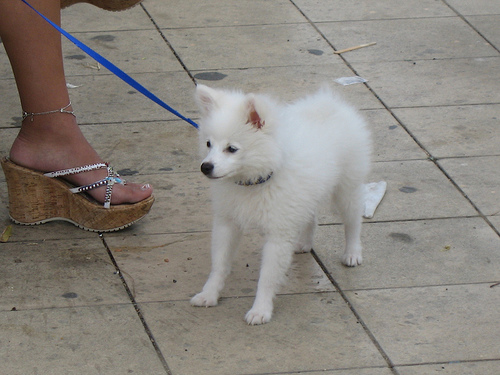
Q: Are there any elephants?
A: No, there are no elephants.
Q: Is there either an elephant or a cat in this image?
A: No, there are no elephants or cats.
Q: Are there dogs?
A: Yes, there is a dog.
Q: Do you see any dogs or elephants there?
A: Yes, there is a dog.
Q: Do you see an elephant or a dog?
A: Yes, there is a dog.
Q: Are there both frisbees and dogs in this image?
A: No, there is a dog but no frisbees.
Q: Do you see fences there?
A: No, there are no fences.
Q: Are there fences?
A: No, there are no fences.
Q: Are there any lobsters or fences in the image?
A: No, there are no fences or lobsters.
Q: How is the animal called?
A: The animal is a dog.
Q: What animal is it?
A: The animal is a dog.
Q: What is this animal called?
A: This is a dog.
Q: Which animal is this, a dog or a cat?
A: This is a dog.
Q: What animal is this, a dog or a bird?
A: This is a dog.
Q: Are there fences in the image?
A: No, there are no fences.